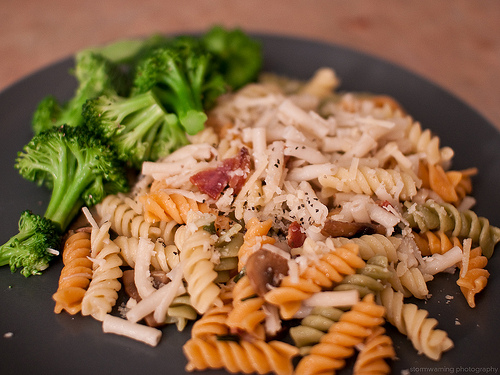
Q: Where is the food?
A: On the plate.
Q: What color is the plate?
A: Black.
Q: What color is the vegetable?
A: Green.